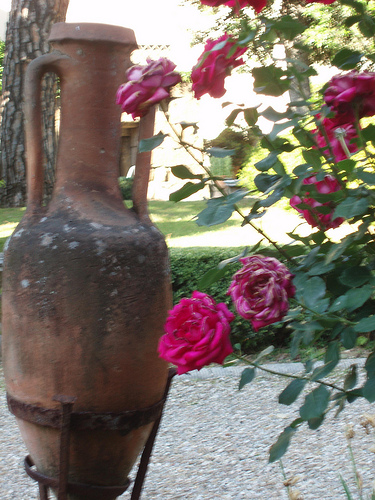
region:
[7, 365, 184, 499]
Metal pot holder in garden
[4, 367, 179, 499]
Rusting metal pot holder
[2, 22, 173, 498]
Clay pot in metal holder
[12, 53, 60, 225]
Handle on clay pot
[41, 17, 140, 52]
Rim of clay pot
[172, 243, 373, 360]
Green hedge along path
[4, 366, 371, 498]
Gravel path through garden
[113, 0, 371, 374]
Red flowers in garden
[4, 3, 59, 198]
Bark on tree trunk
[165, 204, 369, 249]
Bright sunlight on the ground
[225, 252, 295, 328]
bright pink flower that is wilting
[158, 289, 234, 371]
big bright pink rose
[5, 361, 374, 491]
gravel under the flowers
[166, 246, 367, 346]
dark green shrubbery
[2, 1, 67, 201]
large tree trunk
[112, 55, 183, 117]
pink flower that is wilting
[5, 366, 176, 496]
metal base for the pot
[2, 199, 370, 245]
grass on the other side of the shrub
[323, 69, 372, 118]
flower with black parts on the underside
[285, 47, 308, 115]
large tree trunk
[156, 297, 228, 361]
The flower is a rose.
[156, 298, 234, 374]
The flower is pink.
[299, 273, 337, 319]
The leaf is green.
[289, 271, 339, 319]
The leaf is large.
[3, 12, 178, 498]
The vase is brown.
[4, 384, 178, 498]
The vase has a metal base.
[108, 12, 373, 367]
Many flowers are on the bush.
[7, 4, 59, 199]
The trunk is brown.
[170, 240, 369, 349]
The grass is green.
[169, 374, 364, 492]
The ground is gravel.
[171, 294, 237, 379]
pink rose in full bloom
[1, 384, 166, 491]
bottom half of rusted vase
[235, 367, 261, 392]
one green leaf against grey background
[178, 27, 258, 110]
pink flower in sunlight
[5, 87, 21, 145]
long view of brown tree bark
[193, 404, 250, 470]
grey gravel on ground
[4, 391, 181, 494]
metal pot holder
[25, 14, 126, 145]
top of rusty brown vase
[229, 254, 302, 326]
white and pink rose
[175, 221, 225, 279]
top of manicured bush with garden pathway in background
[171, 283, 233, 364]
dark pink roses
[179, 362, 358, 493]
gravel on the ground behind the roses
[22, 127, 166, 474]
clay pot on a metal stand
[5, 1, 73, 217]
very large tree trunk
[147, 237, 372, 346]
green ledge next to street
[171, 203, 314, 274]
patch of green grass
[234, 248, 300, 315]
rose is faded and dying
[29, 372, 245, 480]
metal is rusting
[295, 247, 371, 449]
leaves on rose bushes are green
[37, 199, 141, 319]
moss growing on clay pot